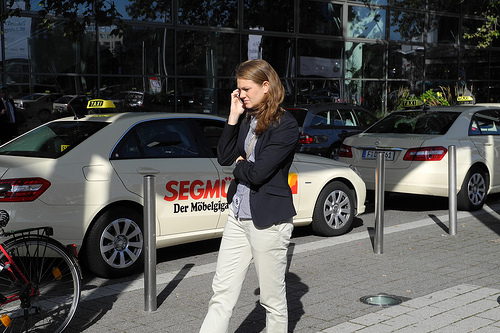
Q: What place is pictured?
A: It is a street.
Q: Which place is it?
A: It is a street.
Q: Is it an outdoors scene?
A: Yes, it is outdoors.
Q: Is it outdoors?
A: Yes, it is outdoors.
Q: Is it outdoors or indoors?
A: It is outdoors.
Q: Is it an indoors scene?
A: No, it is outdoors.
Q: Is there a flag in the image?
A: No, there are no flags.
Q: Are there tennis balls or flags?
A: No, there are no flags or tennis balls.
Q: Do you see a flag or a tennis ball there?
A: No, there are no flags or tennis balls.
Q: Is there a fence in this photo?
A: No, there are no fences.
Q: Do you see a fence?
A: No, there are no fences.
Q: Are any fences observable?
A: No, there are no fences.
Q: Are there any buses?
A: No, there are no buses.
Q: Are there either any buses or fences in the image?
A: No, there are no buses or fences.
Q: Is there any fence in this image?
A: No, there are no fences.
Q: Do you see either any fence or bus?
A: No, there are no fences or buses.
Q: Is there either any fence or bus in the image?
A: No, there are no fences or buses.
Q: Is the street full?
A: Yes, the street is full.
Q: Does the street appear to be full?
A: Yes, the street is full.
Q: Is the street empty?
A: No, the street is full.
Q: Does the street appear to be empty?
A: No, the street is full.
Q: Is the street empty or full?
A: The street is full.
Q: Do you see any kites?
A: No, there are no kites.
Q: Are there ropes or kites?
A: No, there are no kites or ropes.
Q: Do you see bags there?
A: No, there are no bags.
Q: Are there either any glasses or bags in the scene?
A: No, there are no bags or glasses.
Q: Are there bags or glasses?
A: No, there are no bags or glasses.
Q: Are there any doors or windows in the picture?
A: Yes, there is a window.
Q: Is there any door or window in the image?
A: Yes, there is a window.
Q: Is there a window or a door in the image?
A: Yes, there is a window.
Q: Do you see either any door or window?
A: Yes, there is a window.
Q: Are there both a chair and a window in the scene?
A: No, there is a window but no chairs.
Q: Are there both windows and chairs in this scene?
A: No, there is a window but no chairs.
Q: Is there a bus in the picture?
A: No, there are no buses.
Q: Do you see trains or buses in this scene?
A: No, there are no buses or trains.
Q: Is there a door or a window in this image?
A: Yes, there are windows.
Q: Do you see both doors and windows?
A: Yes, there are both windows and a door.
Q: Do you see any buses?
A: No, there are no buses.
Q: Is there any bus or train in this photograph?
A: No, there are no buses or trains.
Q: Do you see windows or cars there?
A: Yes, there is a window.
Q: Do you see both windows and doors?
A: Yes, there are both a window and doors.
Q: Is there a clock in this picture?
A: No, there are no clocks.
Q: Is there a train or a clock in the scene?
A: No, there are no clocks or trains.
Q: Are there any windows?
A: Yes, there is a window.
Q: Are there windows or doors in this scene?
A: Yes, there is a window.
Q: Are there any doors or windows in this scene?
A: Yes, there is a window.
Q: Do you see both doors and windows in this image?
A: Yes, there are both a window and a door.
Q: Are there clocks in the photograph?
A: No, there are no clocks.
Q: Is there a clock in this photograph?
A: No, there are no clocks.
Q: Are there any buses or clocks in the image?
A: No, there are no clocks or buses.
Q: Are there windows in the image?
A: Yes, there is a window.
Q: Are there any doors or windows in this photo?
A: Yes, there is a window.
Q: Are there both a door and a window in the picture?
A: Yes, there are both a window and a door.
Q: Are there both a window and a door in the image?
A: Yes, there are both a window and a door.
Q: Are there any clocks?
A: No, there are no clocks.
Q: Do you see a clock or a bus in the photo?
A: No, there are no clocks or buses.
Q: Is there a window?
A: Yes, there is a window.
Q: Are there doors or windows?
A: Yes, there is a window.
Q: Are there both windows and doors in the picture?
A: Yes, there are both a window and a door.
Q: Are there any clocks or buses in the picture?
A: No, there are no buses or clocks.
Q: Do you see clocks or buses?
A: No, there are no buses or clocks.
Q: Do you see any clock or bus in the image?
A: No, there are no buses or clocks.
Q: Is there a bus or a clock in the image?
A: No, there are no buses or clocks.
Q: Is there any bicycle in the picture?
A: Yes, there is a bicycle.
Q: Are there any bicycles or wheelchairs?
A: Yes, there is a bicycle.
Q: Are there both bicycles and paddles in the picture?
A: No, there is a bicycle but no paddles.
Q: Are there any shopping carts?
A: No, there are no shopping carts.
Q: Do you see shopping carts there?
A: No, there are no shopping carts.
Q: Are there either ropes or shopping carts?
A: No, there are no shopping carts or ropes.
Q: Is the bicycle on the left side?
A: Yes, the bicycle is on the left of the image.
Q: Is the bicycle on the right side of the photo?
A: No, the bicycle is on the left of the image.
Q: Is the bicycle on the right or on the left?
A: The bicycle is on the left of the image.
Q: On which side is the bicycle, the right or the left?
A: The bicycle is on the left of the image.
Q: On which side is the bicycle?
A: The bicycle is on the left of the image.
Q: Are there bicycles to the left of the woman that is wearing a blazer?
A: Yes, there is a bicycle to the left of the woman.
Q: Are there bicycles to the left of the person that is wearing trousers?
A: Yes, there is a bicycle to the left of the woman.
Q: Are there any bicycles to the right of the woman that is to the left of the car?
A: No, the bicycle is to the left of the woman.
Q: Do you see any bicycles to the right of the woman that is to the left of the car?
A: No, the bicycle is to the left of the woman.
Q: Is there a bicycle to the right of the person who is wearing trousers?
A: No, the bicycle is to the left of the woman.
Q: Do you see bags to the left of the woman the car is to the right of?
A: No, there is a bicycle to the left of the woman.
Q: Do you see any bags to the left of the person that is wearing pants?
A: No, there is a bicycle to the left of the woman.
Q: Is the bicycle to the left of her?
A: Yes, the bicycle is to the left of a woman.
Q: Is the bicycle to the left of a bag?
A: No, the bicycle is to the left of a woman.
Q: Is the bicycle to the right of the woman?
A: No, the bicycle is to the left of the woman.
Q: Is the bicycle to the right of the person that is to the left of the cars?
A: No, the bicycle is to the left of the woman.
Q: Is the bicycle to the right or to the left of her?
A: The bicycle is to the left of the woman.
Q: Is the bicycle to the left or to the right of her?
A: The bicycle is to the left of the woman.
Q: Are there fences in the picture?
A: No, there are no fences.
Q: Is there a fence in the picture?
A: No, there are no fences.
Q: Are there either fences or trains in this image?
A: No, there are no fences or trains.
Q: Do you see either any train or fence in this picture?
A: No, there are no fences or trains.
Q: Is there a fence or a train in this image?
A: No, there are no fences or trains.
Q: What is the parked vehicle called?
A: The vehicle is a car.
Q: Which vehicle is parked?
A: The vehicle is a car.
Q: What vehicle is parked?
A: The vehicle is a car.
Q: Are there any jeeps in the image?
A: No, there are no jeeps.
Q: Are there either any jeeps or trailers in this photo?
A: No, there are no jeeps or trailers.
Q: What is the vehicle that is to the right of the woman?
A: The vehicle is a car.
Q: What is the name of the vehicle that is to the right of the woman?
A: The vehicle is a car.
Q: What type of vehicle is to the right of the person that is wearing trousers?
A: The vehicle is a car.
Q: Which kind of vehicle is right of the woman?
A: The vehicle is a car.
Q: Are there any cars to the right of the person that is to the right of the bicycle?
A: Yes, there is a car to the right of the woman.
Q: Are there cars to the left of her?
A: No, the car is to the right of the woman.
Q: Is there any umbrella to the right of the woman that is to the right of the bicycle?
A: No, there is a car to the right of the woman.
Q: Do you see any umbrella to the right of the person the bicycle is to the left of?
A: No, there is a car to the right of the woman.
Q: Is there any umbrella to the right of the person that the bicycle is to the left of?
A: No, there is a car to the right of the woman.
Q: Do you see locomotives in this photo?
A: No, there are no locomotives.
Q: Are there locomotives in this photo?
A: No, there are no locomotives.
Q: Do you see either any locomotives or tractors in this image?
A: No, there are no locomotives or tractors.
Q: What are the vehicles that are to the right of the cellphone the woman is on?
A: The vehicles are cars.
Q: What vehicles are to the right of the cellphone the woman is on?
A: The vehicles are cars.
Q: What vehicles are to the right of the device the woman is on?
A: The vehicles are cars.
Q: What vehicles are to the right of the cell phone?
A: The vehicles are cars.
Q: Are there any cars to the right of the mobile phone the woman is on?
A: Yes, there are cars to the right of the mobile phone.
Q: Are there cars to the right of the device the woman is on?
A: Yes, there are cars to the right of the mobile phone.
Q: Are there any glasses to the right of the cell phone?
A: No, there are cars to the right of the cell phone.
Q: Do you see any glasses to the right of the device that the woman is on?
A: No, there are cars to the right of the cell phone.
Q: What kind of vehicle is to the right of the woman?
A: The vehicles are cars.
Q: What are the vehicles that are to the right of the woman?
A: The vehicles are cars.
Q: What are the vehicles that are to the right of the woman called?
A: The vehicles are cars.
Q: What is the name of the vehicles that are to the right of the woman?
A: The vehicles are cars.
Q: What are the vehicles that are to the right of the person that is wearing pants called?
A: The vehicles are cars.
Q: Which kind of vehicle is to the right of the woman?
A: The vehicles are cars.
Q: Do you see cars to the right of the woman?
A: Yes, there are cars to the right of the woman.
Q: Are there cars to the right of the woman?
A: Yes, there are cars to the right of the woman.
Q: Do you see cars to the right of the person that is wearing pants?
A: Yes, there are cars to the right of the woman.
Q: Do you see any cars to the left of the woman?
A: No, the cars are to the right of the woman.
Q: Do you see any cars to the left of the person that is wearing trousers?
A: No, the cars are to the right of the woman.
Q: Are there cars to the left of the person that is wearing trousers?
A: No, the cars are to the right of the woman.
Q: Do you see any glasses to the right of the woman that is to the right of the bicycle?
A: No, there are cars to the right of the woman.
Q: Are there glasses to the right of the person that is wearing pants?
A: No, there are cars to the right of the woman.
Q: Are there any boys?
A: No, there are no boys.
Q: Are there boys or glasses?
A: No, there are no boys or glasses.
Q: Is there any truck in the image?
A: No, there are no trucks.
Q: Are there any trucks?
A: No, there are no trucks.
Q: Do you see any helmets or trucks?
A: No, there are no trucks or helmets.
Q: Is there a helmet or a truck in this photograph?
A: No, there are no trucks or helmets.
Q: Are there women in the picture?
A: Yes, there is a woman.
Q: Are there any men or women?
A: Yes, there is a woman.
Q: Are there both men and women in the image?
A: No, there is a woman but no men.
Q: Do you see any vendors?
A: No, there are no vendors.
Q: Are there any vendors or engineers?
A: No, there are no vendors or engineers.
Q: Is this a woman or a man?
A: This is a woman.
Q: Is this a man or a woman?
A: This is a woman.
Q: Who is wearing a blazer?
A: The woman is wearing a blazer.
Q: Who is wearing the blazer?
A: The woman is wearing a blazer.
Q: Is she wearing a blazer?
A: Yes, the woman is wearing a blazer.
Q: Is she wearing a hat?
A: No, the woman is wearing a blazer.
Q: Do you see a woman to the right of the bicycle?
A: Yes, there is a woman to the right of the bicycle.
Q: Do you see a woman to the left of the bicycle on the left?
A: No, the woman is to the right of the bicycle.